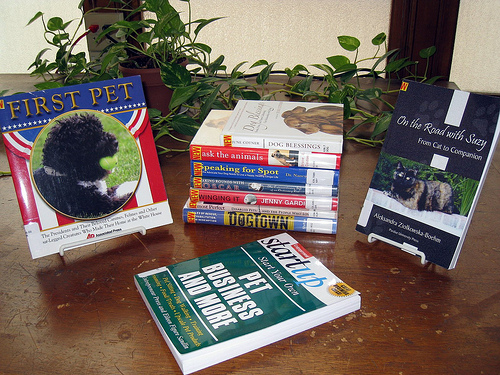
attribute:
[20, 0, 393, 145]
plant — green, growing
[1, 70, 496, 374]
table — old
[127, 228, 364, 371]
book — pet business start-up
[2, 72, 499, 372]
surface — brown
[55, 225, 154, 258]
book stand — white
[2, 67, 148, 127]
top — blue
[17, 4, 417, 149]
plants — green